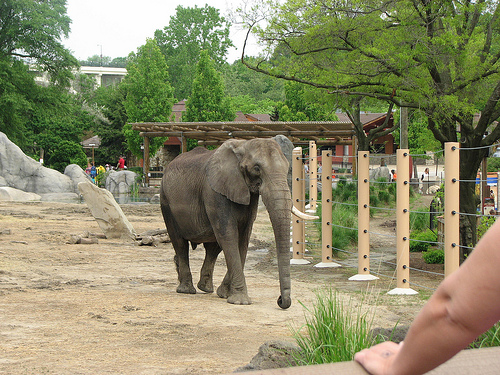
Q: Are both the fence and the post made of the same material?
A: Yes, both the fence and the post are made of wood.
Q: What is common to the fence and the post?
A: The material, both the fence and the post are wooden.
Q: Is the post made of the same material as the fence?
A: Yes, both the post and the fence are made of wood.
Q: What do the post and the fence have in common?
A: The material, both the post and the fence are wooden.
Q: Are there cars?
A: No, there are no cars.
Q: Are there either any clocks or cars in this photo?
A: No, there are no cars or clocks.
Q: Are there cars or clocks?
A: No, there are no cars or clocks.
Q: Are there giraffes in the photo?
A: No, there are no giraffes.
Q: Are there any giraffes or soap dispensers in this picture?
A: No, there are no giraffes or soap dispensers.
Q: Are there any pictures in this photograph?
A: No, there are no pictures.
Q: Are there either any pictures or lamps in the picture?
A: No, there are no pictures or lamps.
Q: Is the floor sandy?
A: Yes, the floor is sandy.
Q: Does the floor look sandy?
A: Yes, the floor is sandy.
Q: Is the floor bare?
A: No, the floor is sandy.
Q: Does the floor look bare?
A: No, the floor is sandy.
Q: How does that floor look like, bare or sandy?
A: The floor is sandy.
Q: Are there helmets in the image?
A: No, there are no helmets.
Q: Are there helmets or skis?
A: No, there are no helmets or skis.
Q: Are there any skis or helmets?
A: No, there are no helmets or skis.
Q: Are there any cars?
A: No, there are no cars.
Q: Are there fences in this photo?
A: Yes, there is a fence.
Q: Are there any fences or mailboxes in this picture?
A: Yes, there is a fence.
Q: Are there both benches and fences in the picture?
A: No, there is a fence but no benches.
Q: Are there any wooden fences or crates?
A: Yes, there is a wood fence.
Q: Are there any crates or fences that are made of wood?
A: Yes, the fence is made of wood.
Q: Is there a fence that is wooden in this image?
A: Yes, there is a wood fence.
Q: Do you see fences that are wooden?
A: Yes, there is a fence that is wooden.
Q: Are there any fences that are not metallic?
A: Yes, there is a wooden fence.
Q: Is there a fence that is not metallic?
A: Yes, there is a wooden fence.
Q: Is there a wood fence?
A: Yes, there is a fence that is made of wood.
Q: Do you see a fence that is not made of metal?
A: Yes, there is a fence that is made of wood.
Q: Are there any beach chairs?
A: No, there are no beach chairs.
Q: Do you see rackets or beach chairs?
A: No, there are no beach chairs or rackets.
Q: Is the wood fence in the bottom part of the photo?
A: Yes, the fence is in the bottom of the image.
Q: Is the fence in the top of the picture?
A: No, the fence is in the bottom of the image.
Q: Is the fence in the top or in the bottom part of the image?
A: The fence is in the bottom of the image.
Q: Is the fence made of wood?
A: Yes, the fence is made of wood.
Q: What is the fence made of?
A: The fence is made of wood.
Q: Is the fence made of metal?
A: No, the fence is made of wood.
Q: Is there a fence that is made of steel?
A: No, there is a fence but it is made of wood.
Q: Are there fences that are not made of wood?
A: No, there is a fence but it is made of wood.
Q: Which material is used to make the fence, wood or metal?
A: The fence is made of wood.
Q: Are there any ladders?
A: No, there are no ladders.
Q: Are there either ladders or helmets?
A: No, there are no ladders or helmets.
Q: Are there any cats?
A: No, there are no cats.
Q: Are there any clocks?
A: No, there are no clocks.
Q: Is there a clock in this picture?
A: No, there are no clocks.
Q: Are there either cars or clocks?
A: No, there are no clocks or cars.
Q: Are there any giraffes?
A: No, there are no giraffes.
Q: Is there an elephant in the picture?
A: Yes, there is an elephant.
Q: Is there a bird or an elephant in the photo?
A: Yes, there is an elephant.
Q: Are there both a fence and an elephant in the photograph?
A: Yes, there are both an elephant and a fence.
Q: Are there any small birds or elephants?
A: Yes, there is a small elephant.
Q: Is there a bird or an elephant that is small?
A: Yes, the elephant is small.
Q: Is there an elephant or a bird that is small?
A: Yes, the elephant is small.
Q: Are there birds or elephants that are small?
A: Yes, the elephant is small.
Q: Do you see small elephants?
A: Yes, there is a small elephant.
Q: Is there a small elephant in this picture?
A: Yes, there is a small elephant.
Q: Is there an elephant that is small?
A: Yes, there is an elephant that is small.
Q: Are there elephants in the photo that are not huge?
A: Yes, there is a small elephant.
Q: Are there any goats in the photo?
A: No, there are no goats.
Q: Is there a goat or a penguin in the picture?
A: No, there are no goats or penguins.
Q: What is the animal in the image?
A: The animal is an elephant.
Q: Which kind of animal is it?
A: The animal is an elephant.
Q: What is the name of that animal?
A: This is an elephant.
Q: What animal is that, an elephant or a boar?
A: This is an elephant.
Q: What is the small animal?
A: The animal is an elephant.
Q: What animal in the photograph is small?
A: The animal is an elephant.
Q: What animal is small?
A: The animal is an elephant.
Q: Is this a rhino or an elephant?
A: This is an elephant.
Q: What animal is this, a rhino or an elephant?
A: This is an elephant.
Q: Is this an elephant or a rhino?
A: This is an elephant.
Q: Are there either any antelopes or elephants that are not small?
A: No, there is an elephant but it is small.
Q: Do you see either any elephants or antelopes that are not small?
A: No, there is an elephant but it is small.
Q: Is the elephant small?
A: Yes, the elephant is small.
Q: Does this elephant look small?
A: Yes, the elephant is small.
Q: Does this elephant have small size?
A: Yes, the elephant is small.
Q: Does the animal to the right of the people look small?
A: Yes, the elephant is small.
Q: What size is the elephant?
A: The elephant is small.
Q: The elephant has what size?
A: The elephant is small.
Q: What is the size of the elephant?
A: The elephant is small.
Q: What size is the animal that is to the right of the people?
A: The elephant is small.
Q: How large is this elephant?
A: The elephant is small.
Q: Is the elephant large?
A: No, the elephant is small.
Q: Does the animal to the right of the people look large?
A: No, the elephant is small.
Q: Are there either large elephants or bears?
A: No, there is an elephant but it is small.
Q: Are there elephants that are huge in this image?
A: No, there is an elephant but it is small.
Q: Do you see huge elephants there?
A: No, there is an elephant but it is small.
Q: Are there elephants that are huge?
A: No, there is an elephant but it is small.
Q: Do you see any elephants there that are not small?
A: No, there is an elephant but it is small.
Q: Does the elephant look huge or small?
A: The elephant is small.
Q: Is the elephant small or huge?
A: The elephant is small.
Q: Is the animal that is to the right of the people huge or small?
A: The elephant is small.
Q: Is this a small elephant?
A: Yes, this is a small elephant.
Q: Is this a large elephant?
A: No, this is a small elephant.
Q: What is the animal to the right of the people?
A: The animal is an elephant.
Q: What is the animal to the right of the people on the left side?
A: The animal is an elephant.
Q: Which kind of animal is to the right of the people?
A: The animal is an elephant.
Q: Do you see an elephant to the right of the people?
A: Yes, there is an elephant to the right of the people.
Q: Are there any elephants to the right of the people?
A: Yes, there is an elephant to the right of the people.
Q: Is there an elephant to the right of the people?
A: Yes, there is an elephant to the right of the people.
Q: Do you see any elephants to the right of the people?
A: Yes, there is an elephant to the right of the people.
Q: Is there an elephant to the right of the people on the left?
A: Yes, there is an elephant to the right of the people.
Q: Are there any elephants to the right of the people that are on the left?
A: Yes, there is an elephant to the right of the people.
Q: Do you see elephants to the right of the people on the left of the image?
A: Yes, there is an elephant to the right of the people.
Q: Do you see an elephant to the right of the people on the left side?
A: Yes, there is an elephant to the right of the people.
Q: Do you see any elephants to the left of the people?
A: No, the elephant is to the right of the people.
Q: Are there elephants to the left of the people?
A: No, the elephant is to the right of the people.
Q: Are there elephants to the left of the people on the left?
A: No, the elephant is to the right of the people.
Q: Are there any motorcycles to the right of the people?
A: No, there is an elephant to the right of the people.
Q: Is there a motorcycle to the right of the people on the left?
A: No, there is an elephant to the right of the people.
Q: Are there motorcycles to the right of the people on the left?
A: No, there is an elephant to the right of the people.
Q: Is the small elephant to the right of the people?
A: Yes, the elephant is to the right of the people.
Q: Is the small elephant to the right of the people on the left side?
A: Yes, the elephant is to the right of the people.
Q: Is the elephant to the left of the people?
A: No, the elephant is to the right of the people.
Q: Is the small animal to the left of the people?
A: No, the elephant is to the right of the people.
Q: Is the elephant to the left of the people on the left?
A: No, the elephant is to the right of the people.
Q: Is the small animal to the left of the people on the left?
A: No, the elephant is to the right of the people.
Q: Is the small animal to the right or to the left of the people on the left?
A: The elephant is to the right of the people.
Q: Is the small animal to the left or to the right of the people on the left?
A: The elephant is to the right of the people.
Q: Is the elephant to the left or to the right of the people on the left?
A: The elephant is to the right of the people.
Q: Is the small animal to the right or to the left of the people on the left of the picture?
A: The elephant is to the right of the people.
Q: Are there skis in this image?
A: No, there are no skis.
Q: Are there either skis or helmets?
A: No, there are no skis or helmets.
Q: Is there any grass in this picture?
A: Yes, there is grass.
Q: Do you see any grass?
A: Yes, there is grass.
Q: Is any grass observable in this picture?
A: Yes, there is grass.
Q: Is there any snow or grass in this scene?
A: Yes, there is grass.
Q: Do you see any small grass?
A: Yes, there is small grass.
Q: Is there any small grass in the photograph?
A: Yes, there is small grass.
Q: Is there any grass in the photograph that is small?
A: Yes, there is grass that is small.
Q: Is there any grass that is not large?
A: Yes, there is small grass.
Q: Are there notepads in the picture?
A: No, there are no notepads.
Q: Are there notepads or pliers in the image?
A: No, there are no notepads or pliers.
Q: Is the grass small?
A: Yes, the grass is small.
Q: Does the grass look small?
A: Yes, the grass is small.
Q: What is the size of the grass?
A: The grass is small.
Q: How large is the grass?
A: The grass is small.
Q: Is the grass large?
A: No, the grass is small.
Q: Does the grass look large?
A: No, the grass is small.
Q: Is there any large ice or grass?
A: No, there is grass but it is small.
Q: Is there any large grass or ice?
A: No, there is grass but it is small.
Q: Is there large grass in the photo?
A: No, there is grass but it is small.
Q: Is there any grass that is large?
A: No, there is grass but it is small.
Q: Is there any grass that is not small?
A: No, there is grass but it is small.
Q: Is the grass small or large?
A: The grass is small.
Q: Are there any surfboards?
A: No, there are no surfboards.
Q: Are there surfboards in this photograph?
A: No, there are no surfboards.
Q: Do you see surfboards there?
A: No, there are no surfboards.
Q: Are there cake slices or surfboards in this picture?
A: No, there are no surfboards or cake slices.